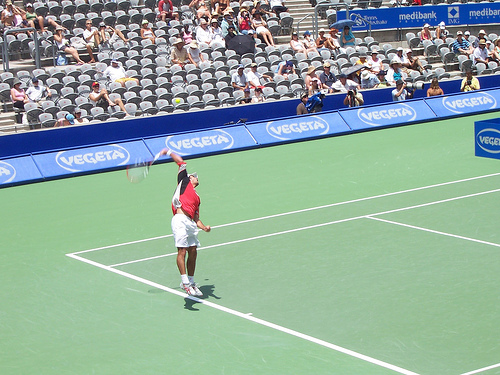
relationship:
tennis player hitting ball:
[161, 151, 213, 302] [173, 96, 183, 103]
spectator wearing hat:
[86, 79, 115, 108] [88, 81, 101, 88]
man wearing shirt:
[462, 70, 479, 91] [464, 79, 478, 90]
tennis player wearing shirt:
[161, 151, 213, 302] [174, 162, 203, 224]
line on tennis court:
[68, 250, 434, 374] [5, 107, 498, 374]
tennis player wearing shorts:
[161, 151, 213, 302] [173, 213, 202, 251]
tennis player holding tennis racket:
[161, 151, 213, 302] [127, 150, 165, 184]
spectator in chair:
[86, 79, 115, 108] [172, 84, 187, 100]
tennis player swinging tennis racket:
[161, 151, 213, 302] [127, 150, 165, 184]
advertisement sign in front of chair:
[266, 113, 329, 139] [172, 84, 187, 100]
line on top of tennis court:
[68, 250, 434, 374] [5, 107, 498, 374]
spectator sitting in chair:
[86, 79, 115, 108] [88, 93, 102, 104]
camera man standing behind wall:
[395, 82, 414, 101] [7, 87, 499, 187]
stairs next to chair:
[287, 6, 329, 40] [172, 84, 187, 100]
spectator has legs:
[86, 79, 115, 108] [103, 95, 120, 109]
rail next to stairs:
[290, 13, 322, 38] [287, 6, 329, 40]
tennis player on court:
[161, 151, 213, 302] [17, 119, 481, 365]